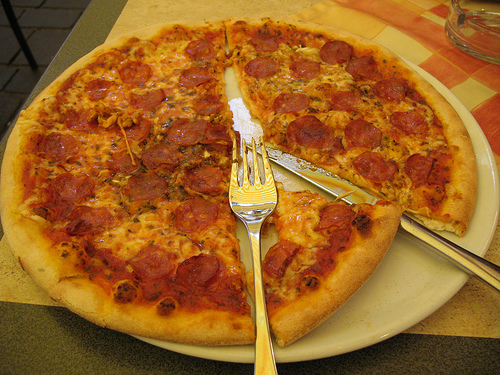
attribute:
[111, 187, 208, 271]
cheese — melted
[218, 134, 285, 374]
fork — silver 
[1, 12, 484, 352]
pizza — pepperoni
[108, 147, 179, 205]
pepperoni — red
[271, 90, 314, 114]
pepperoni — red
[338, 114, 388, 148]
pepperoni — red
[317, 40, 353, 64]
pepperoni — red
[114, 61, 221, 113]
pepperoni — red